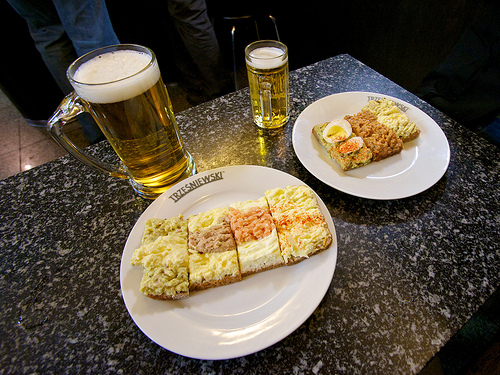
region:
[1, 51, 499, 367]
A black granite counter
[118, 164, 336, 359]
A white plate with food on it.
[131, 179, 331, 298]
Pastries on a plate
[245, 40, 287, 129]
A small mug filled with beer.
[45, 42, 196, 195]
A large mug filled with beer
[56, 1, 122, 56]
A pair of blue jeans.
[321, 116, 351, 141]
A deviled egg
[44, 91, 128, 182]
A glass handle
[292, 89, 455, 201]
A small plate with various food on it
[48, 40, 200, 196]
A mug containing an amber beer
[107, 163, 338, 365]
white plate full of food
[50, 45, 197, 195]
large glass of amber beer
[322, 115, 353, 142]
half of a hardboiled egg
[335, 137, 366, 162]
red paprika on egg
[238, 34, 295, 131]
small glass of beer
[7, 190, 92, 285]
black and white speckled counter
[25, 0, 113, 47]
a pair of blue jeans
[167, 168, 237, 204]
Black print on white plate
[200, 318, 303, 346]
Light reflecting off plate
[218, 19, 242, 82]
metal leg of chair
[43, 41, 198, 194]
this a glass of beer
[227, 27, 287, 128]
this a glass of beer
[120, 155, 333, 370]
this is a white plate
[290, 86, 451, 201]
this is a white plate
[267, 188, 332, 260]
this a slice of cake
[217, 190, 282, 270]
this a slice of cake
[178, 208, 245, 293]
this a slice of cake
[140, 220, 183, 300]
this a slice of cake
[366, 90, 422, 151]
this a slice of cake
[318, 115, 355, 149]
this is a piece of egg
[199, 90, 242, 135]
part of a wall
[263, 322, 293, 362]
edge of a dish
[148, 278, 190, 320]
edge of a cake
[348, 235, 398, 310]
part of a floor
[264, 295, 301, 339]
edge of a plate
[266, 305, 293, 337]
part of a plate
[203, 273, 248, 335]
edge of a plate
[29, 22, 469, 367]
beer and food on a table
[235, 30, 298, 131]
a glass of beer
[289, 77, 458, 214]
a white dish with snacks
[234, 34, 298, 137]
beer has foam on top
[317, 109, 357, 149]
half of an egg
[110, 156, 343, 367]
a big dish with four pieces of pie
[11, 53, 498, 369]
a table color salt and pepper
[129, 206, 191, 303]
yellow sauce on top of pie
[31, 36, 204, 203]
a glass of beer next to a white dish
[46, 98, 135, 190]
handle of a glass